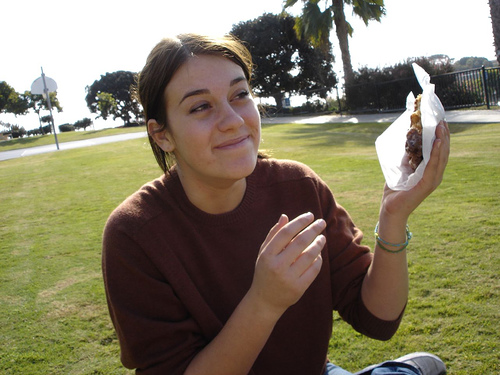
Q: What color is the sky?
A: White.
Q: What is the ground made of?
A: Grass.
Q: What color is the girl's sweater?
A: Brown.